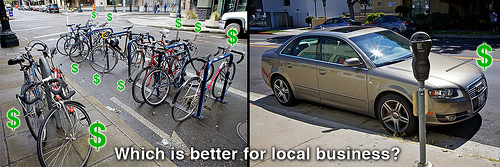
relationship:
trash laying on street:
[101, 95, 126, 125] [44, 7, 240, 143]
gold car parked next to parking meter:
[260, 25, 489, 137] [406, 31, 434, 165]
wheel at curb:
[370, 84, 423, 142] [251, 86, 499, 166]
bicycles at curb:
[70, 14, 237, 125] [2, 34, 181, 164]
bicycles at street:
[70, 14, 237, 125] [18, 14, 246, 158]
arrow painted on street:
[107, 93, 194, 157] [18, 14, 246, 158]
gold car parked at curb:
[260, 25, 489, 137] [251, 102, 498, 162]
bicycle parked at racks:
[169, 44, 244, 124] [14, 22, 232, 140]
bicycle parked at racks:
[17, 57, 94, 165] [14, 22, 232, 140]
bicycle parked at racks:
[7, 39, 51, 142] [14, 22, 232, 140]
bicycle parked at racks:
[89, 22, 137, 73] [14, 22, 232, 140]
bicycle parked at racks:
[124, 30, 157, 80] [14, 22, 232, 140]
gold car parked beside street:
[260, 25, 489, 137] [3, 7, 246, 138]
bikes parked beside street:
[54, 19, 244, 124] [18, 14, 246, 158]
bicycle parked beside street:
[17, 57, 94, 165] [18, 14, 246, 158]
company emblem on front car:
[474, 80, 484, 96] [290, 24, 458, 116]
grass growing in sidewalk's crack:
[446, 142, 498, 163] [383, 131, 494, 163]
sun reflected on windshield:
[343, 29, 445, 84] [310, 21, 447, 72]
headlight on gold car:
[428, 85, 455, 101] [260, 25, 489, 137]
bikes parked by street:
[54, 19, 244, 124] [18, 14, 246, 158]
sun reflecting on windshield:
[368, 46, 388, 61] [347, 29, 415, 63]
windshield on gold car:
[347, 29, 415, 63] [260, 25, 489, 137]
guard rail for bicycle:
[198, 47, 238, 120] [169, 44, 244, 124]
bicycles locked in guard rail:
[62, 19, 231, 129] [192, 53, 235, 120]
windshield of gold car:
[347, 30, 412, 68] [260, 25, 489, 137]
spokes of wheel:
[45, 111, 96, 162] [40, 81, 114, 163]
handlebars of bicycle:
[18, 66, 77, 111] [7, 52, 109, 163]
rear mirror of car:
[339, 45, 370, 85] [248, 24, 498, 149]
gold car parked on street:
[253, 12, 490, 148] [253, 35, 498, 157]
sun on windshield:
[368, 46, 388, 61] [347, 30, 412, 68]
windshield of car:
[347, 30, 412, 68] [260, 19, 490, 152]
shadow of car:
[275, 94, 473, 163] [274, 16, 463, 127]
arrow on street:
[107, 93, 194, 157] [18, 14, 246, 158]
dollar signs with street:
[64, 59, 126, 91] [27, 0, 243, 153]